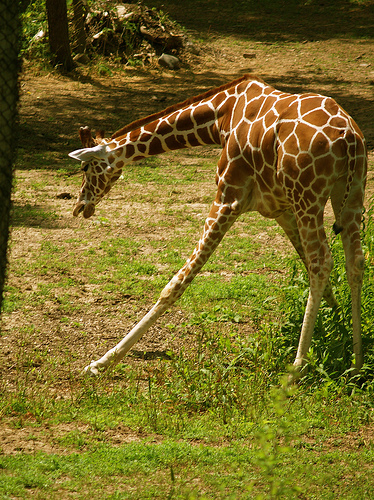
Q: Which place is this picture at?
A: It is at the field.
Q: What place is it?
A: It is a field.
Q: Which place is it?
A: It is a field.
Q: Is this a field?
A: Yes, it is a field.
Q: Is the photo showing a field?
A: Yes, it is showing a field.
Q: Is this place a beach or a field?
A: It is a field.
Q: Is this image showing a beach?
A: No, the picture is showing a field.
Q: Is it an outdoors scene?
A: Yes, it is outdoors.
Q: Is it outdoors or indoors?
A: It is outdoors.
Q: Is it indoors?
A: No, it is outdoors.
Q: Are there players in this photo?
A: No, there are no players.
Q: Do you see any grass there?
A: Yes, there is grass.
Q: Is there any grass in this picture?
A: Yes, there is grass.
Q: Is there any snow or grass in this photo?
A: Yes, there is grass.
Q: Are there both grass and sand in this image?
A: No, there is grass but no sand.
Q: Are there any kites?
A: No, there are no kites.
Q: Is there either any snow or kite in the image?
A: No, there are no kites or snow.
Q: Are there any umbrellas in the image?
A: No, there are no umbrellas.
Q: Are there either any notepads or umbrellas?
A: No, there are no umbrellas or notepads.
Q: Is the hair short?
A: Yes, the hair is short.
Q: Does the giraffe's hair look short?
A: Yes, the hair is short.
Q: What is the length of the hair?
A: The hair is short.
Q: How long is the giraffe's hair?
A: The hair is short.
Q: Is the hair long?
A: No, the hair is short.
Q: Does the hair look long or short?
A: The hair is short.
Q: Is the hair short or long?
A: The hair is short.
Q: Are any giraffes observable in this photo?
A: Yes, there is a giraffe.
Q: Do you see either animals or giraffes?
A: Yes, there is a giraffe.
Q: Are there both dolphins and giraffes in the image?
A: No, there is a giraffe but no dolphins.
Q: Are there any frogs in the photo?
A: No, there are no frogs.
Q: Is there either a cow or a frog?
A: No, there are no frogs or cows.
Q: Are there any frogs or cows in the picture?
A: No, there are no frogs or cows.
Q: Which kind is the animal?
A: The animal is a giraffe.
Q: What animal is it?
A: The animal is a giraffe.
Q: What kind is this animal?
A: This is a giraffe.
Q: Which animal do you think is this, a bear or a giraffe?
A: This is a giraffe.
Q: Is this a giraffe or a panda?
A: This is a giraffe.